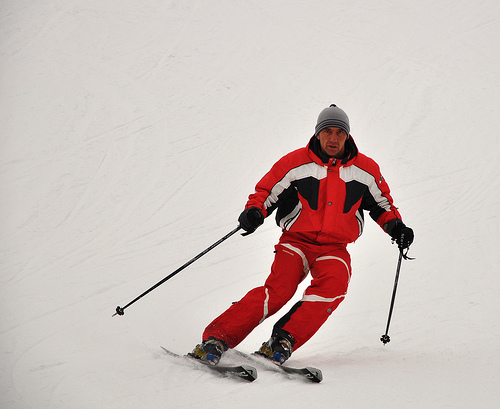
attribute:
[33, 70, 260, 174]
snow — deep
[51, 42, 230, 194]
snow — bright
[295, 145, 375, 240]
jacket — white, red, black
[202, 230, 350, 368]
pants — red